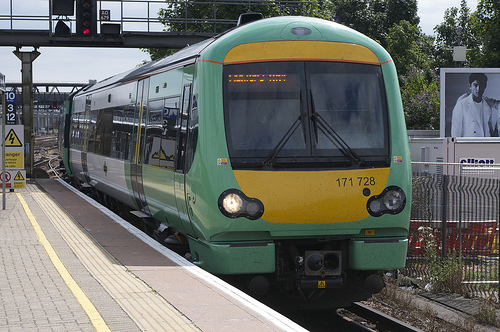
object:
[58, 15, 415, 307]
train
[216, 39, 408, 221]
front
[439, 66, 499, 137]
ad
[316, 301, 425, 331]
tracks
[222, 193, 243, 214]
light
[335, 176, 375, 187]
numbers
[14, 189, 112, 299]
stripe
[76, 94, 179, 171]
windows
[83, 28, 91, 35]
light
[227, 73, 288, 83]
display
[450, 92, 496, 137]
shirt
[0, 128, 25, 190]
warning sign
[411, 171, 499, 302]
fence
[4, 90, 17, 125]
sign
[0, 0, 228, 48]
crosswalk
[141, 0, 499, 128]
trees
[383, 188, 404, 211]
light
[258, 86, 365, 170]
wipers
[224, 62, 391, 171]
windshield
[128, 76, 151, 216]
door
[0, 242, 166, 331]
curb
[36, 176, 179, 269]
shadow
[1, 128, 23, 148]
triangle